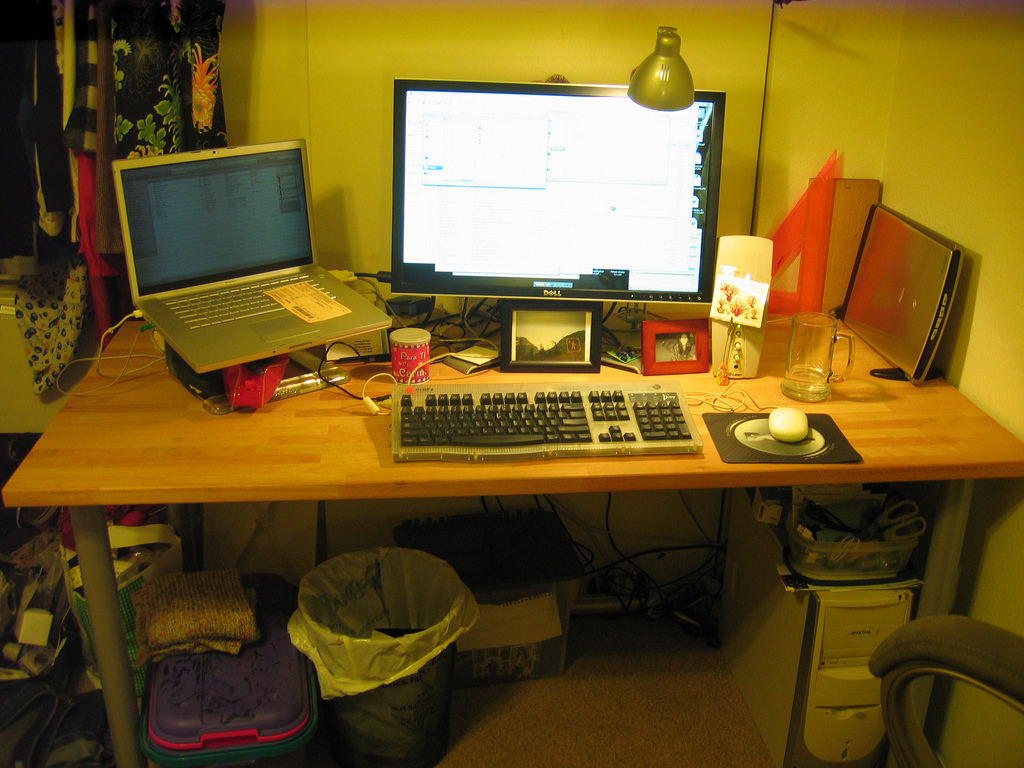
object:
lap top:
[107, 132, 397, 377]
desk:
[0, 255, 1019, 515]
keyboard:
[383, 369, 710, 468]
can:
[289, 535, 486, 763]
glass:
[769, 302, 867, 407]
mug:
[778, 309, 860, 405]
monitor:
[385, 79, 728, 302]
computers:
[352, 64, 738, 383]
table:
[0, 264, 1023, 515]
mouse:
[765, 405, 811, 445]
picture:
[638, 313, 711, 378]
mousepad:
[698, 408, 866, 467]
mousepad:
[495, 289, 610, 379]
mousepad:
[636, 314, 719, 379]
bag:
[273, 533, 490, 706]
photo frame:
[633, 315, 715, 379]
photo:
[648, 329, 700, 364]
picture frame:
[495, 291, 605, 376]